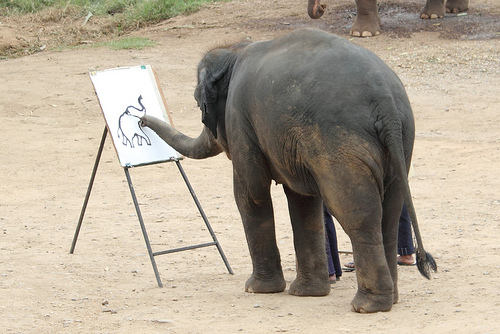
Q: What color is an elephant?
A: Gray.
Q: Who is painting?
A: An elephant.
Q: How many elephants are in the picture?
A: One.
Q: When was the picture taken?
A: Daytime.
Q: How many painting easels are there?
A: Only one.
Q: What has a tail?
A: The elephant.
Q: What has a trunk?
A: Elephant.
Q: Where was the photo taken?
A: At a zoo.